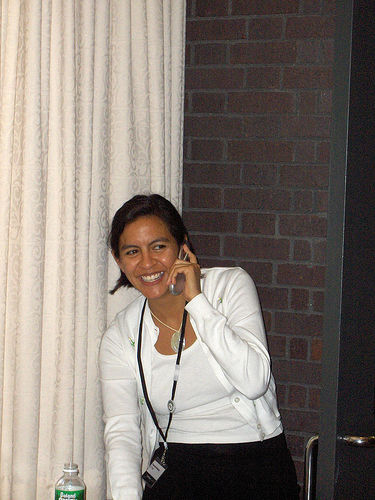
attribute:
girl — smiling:
[99, 196, 301, 499]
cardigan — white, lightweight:
[100, 267, 283, 499]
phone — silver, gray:
[168, 233, 190, 295]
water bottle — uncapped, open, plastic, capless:
[55, 463, 87, 499]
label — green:
[55, 490, 88, 498]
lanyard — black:
[138, 300, 189, 488]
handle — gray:
[303, 437, 319, 499]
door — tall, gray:
[316, 0, 374, 500]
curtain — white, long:
[1, 1, 186, 499]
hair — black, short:
[110, 196, 198, 296]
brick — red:
[191, 41, 228, 66]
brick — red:
[246, 67, 282, 88]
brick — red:
[285, 13, 334, 40]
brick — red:
[280, 163, 330, 192]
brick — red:
[227, 141, 293, 166]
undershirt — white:
[148, 339, 282, 449]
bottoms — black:
[144, 432, 300, 498]